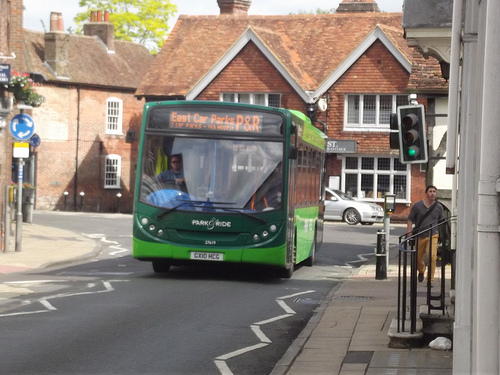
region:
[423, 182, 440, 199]
the head of a man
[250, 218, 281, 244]
headlights on a bus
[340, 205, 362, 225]
a black and silver car wheel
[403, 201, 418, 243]
the arm of a man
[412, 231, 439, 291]
a pair of yellow pants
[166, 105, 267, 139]
the electronic bus display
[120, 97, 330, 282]
a green bus on the street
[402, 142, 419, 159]
a green go light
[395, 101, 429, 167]
a set of traffic lights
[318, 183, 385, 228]
a silver car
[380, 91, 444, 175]
a green bus heading to East Car Parks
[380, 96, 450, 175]
a stoplight is green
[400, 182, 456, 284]
a man with yellow pants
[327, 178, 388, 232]
gray car behind the bus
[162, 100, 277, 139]
marquee indicating bus destination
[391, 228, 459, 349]
steps leading into a building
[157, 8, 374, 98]
a building with a shingled roof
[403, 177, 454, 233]
a man with a gray shirt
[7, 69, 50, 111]
flowers hanging from a street post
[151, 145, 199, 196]
the bus driver wears a blue shirt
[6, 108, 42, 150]
Blue and white roundabout street sign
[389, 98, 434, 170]
Green traffic light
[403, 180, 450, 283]
Pedestrian wearing yellow pants and grey shirt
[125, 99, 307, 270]
Green bus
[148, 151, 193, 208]
Bus driver wearing sunglasses and blue shirt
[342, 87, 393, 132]
Windows with white trim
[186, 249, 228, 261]
License plate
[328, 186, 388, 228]
Silver vehicle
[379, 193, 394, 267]
Parking meter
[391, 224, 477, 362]
Railing and steps of porch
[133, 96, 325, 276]
a green bus on the street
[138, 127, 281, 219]
the bus's windshield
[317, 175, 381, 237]
a grey car is parked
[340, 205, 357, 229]
the car's tire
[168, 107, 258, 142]
writings on the bus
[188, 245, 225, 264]
a black and white number plate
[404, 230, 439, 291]
brown pants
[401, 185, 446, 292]
a person walking in the street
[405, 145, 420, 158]
a green light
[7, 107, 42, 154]
a sign on the street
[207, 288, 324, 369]
white zigzag lines on the street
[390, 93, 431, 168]
street light showing green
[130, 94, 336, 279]
a green city bus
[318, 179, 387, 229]
front end of a silver car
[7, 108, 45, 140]
a round blue sign with white arrows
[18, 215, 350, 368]
a narrow tar road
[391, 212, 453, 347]
steps with a metal railing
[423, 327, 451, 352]
a big white rock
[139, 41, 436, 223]
building made of bricks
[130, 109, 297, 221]
large front window on a bus